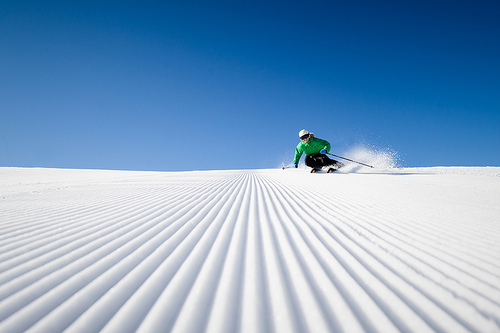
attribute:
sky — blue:
[1, 0, 498, 172]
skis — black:
[307, 160, 345, 176]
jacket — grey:
[294, 137, 329, 164]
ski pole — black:
[323, 146, 377, 170]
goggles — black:
[283, 124, 330, 146]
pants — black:
[299, 146, 349, 181]